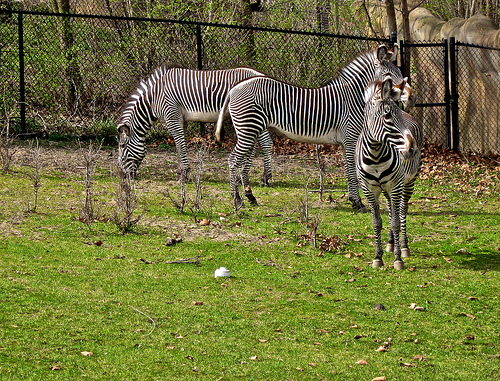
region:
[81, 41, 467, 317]
thre zebras on the grass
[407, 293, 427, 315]
leaf on the grass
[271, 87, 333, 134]
black and white stripes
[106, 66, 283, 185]
zebra grazing in the grass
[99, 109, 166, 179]
head in the grass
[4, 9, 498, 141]
black chain link fence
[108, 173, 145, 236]
small brown plant jutting out of the grass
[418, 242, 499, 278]
shadow from the zebra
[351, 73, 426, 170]
head angled to the side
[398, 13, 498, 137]
large rock formation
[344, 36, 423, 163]
compact zebra's face blocks much of larger zebra's face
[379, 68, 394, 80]
unblocked eye of larger zebra is smiling [you'll see]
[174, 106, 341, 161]
the soft white underbellies of @ least two mammals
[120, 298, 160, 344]
a small thin branch on the ground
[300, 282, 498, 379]
small smattering of leaves @ right front grass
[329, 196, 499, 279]
shadow of compact zebra a bit in front of shadow of larger zebra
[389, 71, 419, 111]
a brown+white pointy ear in front of a brown+white horsey nose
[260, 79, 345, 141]
very straight stripes on the middle zebra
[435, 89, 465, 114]
the closed lock of the door in the gate of the chainlink fence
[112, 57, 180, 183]
zebra @ back ignores us all to chomp grass+weeds+whatever park guests may have thrown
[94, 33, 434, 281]
Three zebras standing up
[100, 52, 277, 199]
One zebra eating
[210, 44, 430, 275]
Two black and white striped zebras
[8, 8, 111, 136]
Chain link fence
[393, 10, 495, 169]
Concrete wall behind a chain link fence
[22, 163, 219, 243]
Several small dead looking bushes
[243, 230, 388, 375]
Green grass and dead leaves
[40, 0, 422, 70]
Narrow trees beyond the fence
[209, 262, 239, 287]
White capped pipe in the ground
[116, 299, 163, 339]
Dead tree branch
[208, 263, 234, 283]
a ball, a bird, a piece of trash? whatever it is, it's white-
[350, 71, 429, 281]
compact zebra distracted by something to its left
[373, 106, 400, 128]
zebra has dark melancholy eye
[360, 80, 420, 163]
zebra has brown+white mane, brown+white nose, some black stripes between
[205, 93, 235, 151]
zebra has a fairly short tail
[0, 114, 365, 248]
some dry & presently inert plants before+beside zebras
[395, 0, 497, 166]
black chain link fence borders zoo's high fake rock ridge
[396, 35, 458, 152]
door near the ridge, in the chainlink fence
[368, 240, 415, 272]
light grey hooves on distracted little zebra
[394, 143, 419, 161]
look close @ little zebra's mouth, you'll see him smiling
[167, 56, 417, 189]
Three zebras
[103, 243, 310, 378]
The zebras are standing on the green grass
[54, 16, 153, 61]
A black fence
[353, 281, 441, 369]
Leaves on the green grass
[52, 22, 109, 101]
Tree trunks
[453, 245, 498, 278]
The shadow of the zebra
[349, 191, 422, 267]
the legs of the zebra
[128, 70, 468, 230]
the zebras are black and white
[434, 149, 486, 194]
brown leaves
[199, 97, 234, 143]
the tail of the zebra